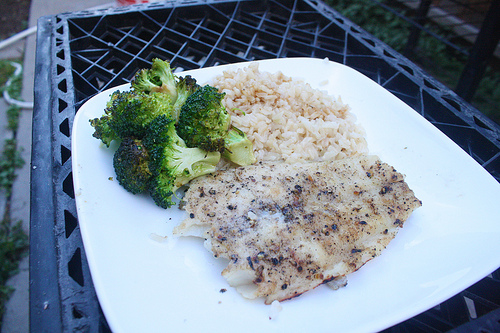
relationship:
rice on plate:
[212, 56, 362, 158] [66, 69, 496, 329]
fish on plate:
[205, 106, 407, 253] [66, 69, 496, 329]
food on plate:
[89, 55, 421, 305] [66, 69, 496, 329]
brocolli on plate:
[112, 122, 203, 204] [97, 205, 209, 328]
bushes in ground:
[423, 31, 453, 59] [0, 179, 33, 270]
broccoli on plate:
[89, 54, 254, 204] [66, 69, 496, 329]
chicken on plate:
[178, 137, 429, 307] [66, 69, 496, 329]